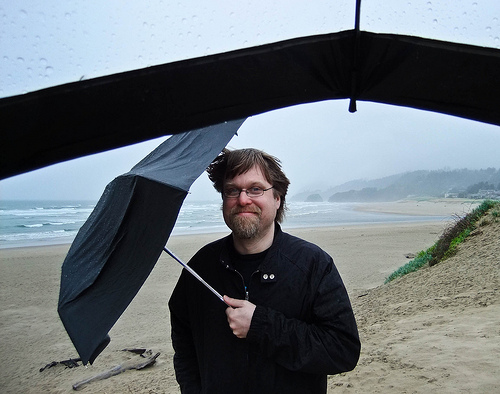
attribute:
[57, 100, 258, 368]
umbrella — wrinkled, black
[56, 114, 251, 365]
umbrella — black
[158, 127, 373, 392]
jacket — black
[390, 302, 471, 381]
sand — brown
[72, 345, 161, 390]
wood — old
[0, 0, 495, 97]
drops — rain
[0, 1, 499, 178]
umbrella — clear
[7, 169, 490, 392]
beach — steep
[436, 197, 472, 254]
grass — gras